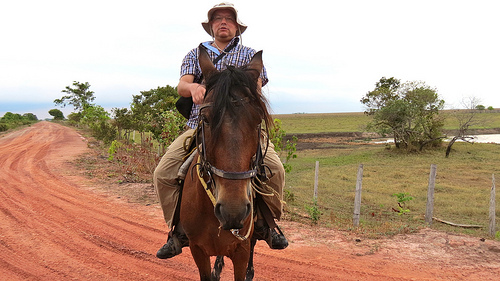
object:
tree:
[52, 80, 98, 125]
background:
[0, 0, 498, 162]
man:
[150, 2, 289, 259]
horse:
[179, 44, 272, 281]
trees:
[47, 108, 68, 121]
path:
[0, 120, 499, 281]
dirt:
[0, 119, 499, 280]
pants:
[152, 126, 286, 232]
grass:
[262, 108, 499, 243]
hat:
[200, 2, 248, 37]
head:
[211, 9, 239, 42]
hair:
[198, 64, 276, 157]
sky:
[0, 0, 500, 122]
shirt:
[179, 36, 269, 130]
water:
[371, 132, 499, 144]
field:
[259, 108, 499, 241]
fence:
[278, 160, 499, 243]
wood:
[488, 172, 495, 238]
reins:
[188, 96, 276, 241]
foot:
[155, 228, 192, 260]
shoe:
[155, 228, 191, 260]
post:
[351, 164, 364, 227]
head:
[195, 42, 272, 231]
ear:
[197, 42, 221, 80]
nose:
[212, 198, 253, 229]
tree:
[359, 76, 445, 152]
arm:
[175, 47, 198, 98]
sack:
[175, 36, 241, 121]